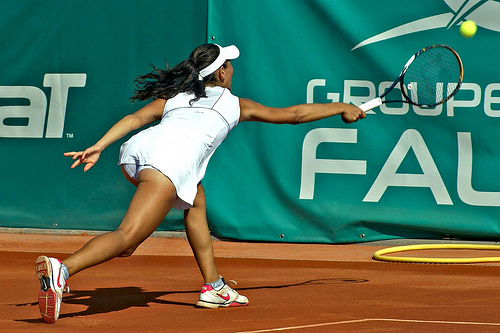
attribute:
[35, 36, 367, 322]
woman — hitting, bending, reaching, playing, stretched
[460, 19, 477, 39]
ball — green, small, yellow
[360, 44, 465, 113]
racket — black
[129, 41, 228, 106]
hair — black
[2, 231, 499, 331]
floor — brown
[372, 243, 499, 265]
circle — ground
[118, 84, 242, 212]
dress — white, official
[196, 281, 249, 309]
shoe — white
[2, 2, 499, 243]
banner — an ad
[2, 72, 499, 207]
lettering — white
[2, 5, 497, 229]
sign — green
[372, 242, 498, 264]
hose — yellow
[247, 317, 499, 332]
line — white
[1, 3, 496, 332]
picture — taken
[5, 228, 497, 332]
court — brown